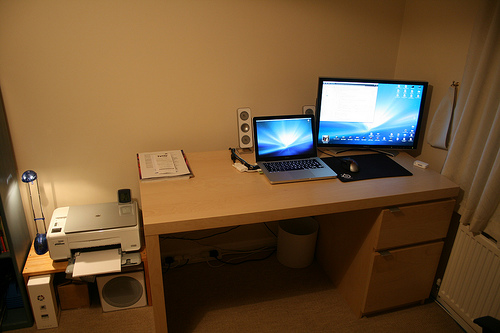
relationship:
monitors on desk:
[248, 76, 440, 184] [142, 163, 463, 329]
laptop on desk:
[253, 115, 332, 184] [142, 163, 463, 329]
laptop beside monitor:
[253, 115, 332, 184] [315, 76, 429, 150]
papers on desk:
[132, 148, 201, 180] [142, 163, 463, 329]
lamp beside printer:
[18, 167, 51, 256] [46, 195, 143, 278]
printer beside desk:
[46, 195, 143, 278] [142, 163, 463, 329]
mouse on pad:
[338, 156, 362, 172] [334, 153, 413, 184]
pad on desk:
[334, 153, 413, 184] [142, 163, 463, 329]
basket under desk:
[271, 225, 326, 277] [142, 163, 463, 329]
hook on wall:
[444, 75, 461, 89] [27, 11, 312, 101]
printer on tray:
[46, 195, 143, 278] [23, 255, 155, 323]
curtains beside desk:
[462, 24, 489, 229] [142, 163, 463, 329]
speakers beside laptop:
[234, 109, 254, 151] [253, 115, 332, 184]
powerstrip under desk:
[165, 241, 239, 278] [142, 163, 463, 329]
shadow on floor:
[191, 273, 325, 322] [177, 268, 343, 333]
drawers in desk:
[367, 199, 459, 315] [142, 163, 463, 329]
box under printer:
[56, 280, 93, 314] [46, 195, 143, 278]